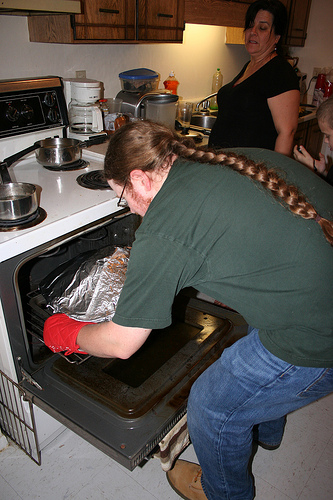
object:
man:
[38, 118, 332, 498]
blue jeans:
[186, 330, 333, 498]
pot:
[34, 135, 86, 170]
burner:
[43, 155, 88, 171]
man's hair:
[104, 125, 333, 236]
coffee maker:
[68, 76, 104, 138]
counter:
[83, 121, 213, 165]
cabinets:
[25, 6, 187, 42]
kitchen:
[2, 1, 332, 499]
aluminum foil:
[42, 241, 134, 323]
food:
[47, 240, 147, 331]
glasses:
[112, 180, 130, 207]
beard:
[128, 189, 151, 218]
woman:
[207, 1, 302, 154]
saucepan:
[0, 182, 42, 220]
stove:
[0, 76, 250, 475]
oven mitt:
[43, 312, 97, 356]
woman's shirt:
[209, 56, 302, 150]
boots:
[167, 457, 212, 499]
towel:
[152, 408, 193, 471]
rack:
[0, 372, 42, 464]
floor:
[0, 392, 333, 500]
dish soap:
[163, 70, 179, 96]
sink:
[180, 108, 219, 129]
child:
[293, 99, 333, 177]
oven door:
[25, 300, 251, 472]